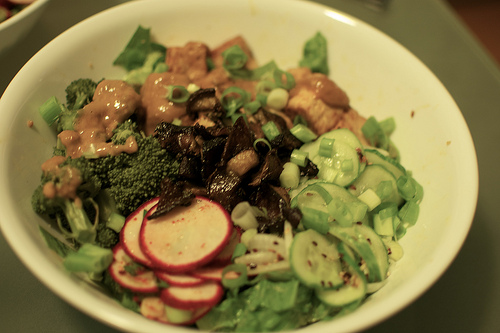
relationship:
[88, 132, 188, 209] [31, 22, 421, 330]
broccoli head in a salad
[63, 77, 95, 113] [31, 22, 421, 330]
broccoli head in a salad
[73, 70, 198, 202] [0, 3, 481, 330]
vinaigrette on bowl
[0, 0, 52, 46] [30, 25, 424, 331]
bowl containing food